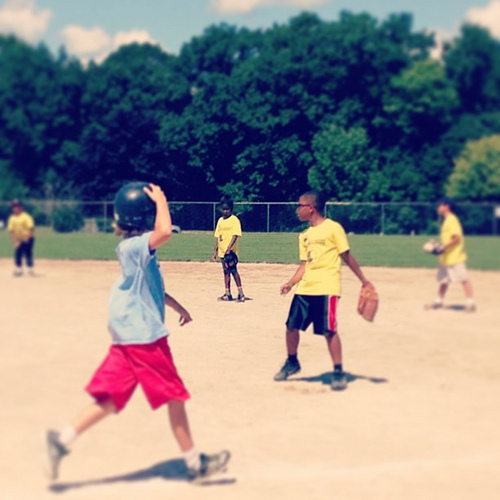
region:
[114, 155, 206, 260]
black helmet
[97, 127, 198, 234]
black helmet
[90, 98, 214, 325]
black helmet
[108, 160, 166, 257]
black helmet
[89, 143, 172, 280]
black helmet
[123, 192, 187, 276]
black helmet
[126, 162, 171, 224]
black helmet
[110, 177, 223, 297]
black helmet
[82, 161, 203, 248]
boy in black helmet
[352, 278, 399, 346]
brown baseball mitt in photo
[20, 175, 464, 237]
fence in background of photo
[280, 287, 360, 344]
boy in black and red shorts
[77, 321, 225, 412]
boy in red shorts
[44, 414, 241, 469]
boy wearing white socks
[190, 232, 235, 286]
boy in black shorts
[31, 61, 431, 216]
trees in background of photo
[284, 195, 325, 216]
black eye glasses on boys face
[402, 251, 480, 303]
boy wearing khaki shorts